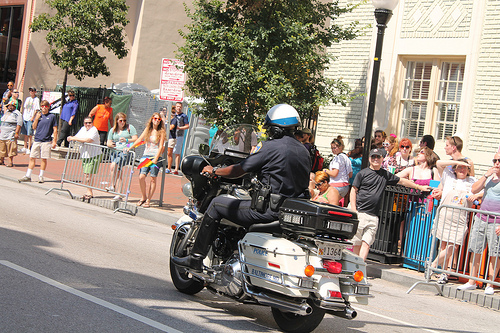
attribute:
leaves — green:
[79, 38, 84, 41]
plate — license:
[314, 242, 345, 259]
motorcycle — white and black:
[168, 151, 374, 332]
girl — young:
[320, 133, 356, 209]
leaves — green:
[179, 3, 365, 108]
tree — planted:
[181, 0, 367, 151]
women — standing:
[108, 110, 166, 195]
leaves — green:
[207, 16, 269, 63]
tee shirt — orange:
[88, 105, 115, 131]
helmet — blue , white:
[262, 97, 303, 142]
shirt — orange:
[95, 105, 110, 128]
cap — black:
[370, 149, 384, 156]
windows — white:
[411, 51, 495, 139]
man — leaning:
[350, 145, 428, 260]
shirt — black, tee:
[332, 150, 409, 214]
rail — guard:
[368, 175, 484, 286]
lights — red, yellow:
[297, 253, 381, 285]